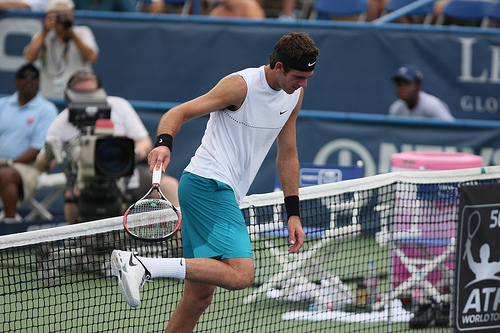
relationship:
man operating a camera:
[35, 68, 184, 242] [63, 90, 142, 278]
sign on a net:
[439, 182, 485, 323] [20, 171, 482, 321]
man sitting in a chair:
[0, 64, 58, 225] [19, 158, 64, 227]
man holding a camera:
[19, 0, 100, 104] [52, 10, 78, 40]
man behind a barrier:
[384, 57, 467, 123] [309, 114, 479, 212]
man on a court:
[106, 31, 321, 333] [25, 125, 472, 317]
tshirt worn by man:
[180, 67, 307, 200] [106, 31, 321, 333]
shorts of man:
[178, 168, 258, 261] [106, 31, 321, 333]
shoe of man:
[111, 249, 147, 309] [97, 23, 323, 330]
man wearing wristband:
[106, 31, 321, 333] [281, 191, 303, 217]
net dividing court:
[2, 166, 452, 331] [6, 208, 423, 329]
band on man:
[270, 51, 318, 73] [106, 31, 321, 333]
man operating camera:
[35, 68, 184, 242] [64, 70, 135, 224]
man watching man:
[0, 64, 58, 225] [106, 31, 321, 333]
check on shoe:
[128, 253, 137, 266] [107, 249, 148, 305]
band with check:
[270, 51, 318, 73] [308, 61, 316, 67]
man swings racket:
[106, 31, 321, 333] [119, 158, 183, 242]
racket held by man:
[119, 158, 183, 242] [111, 32, 318, 326]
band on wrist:
[284, 195, 301, 220] [288, 204, 298, 222]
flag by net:
[444, 183, 484, 328] [2, 166, 452, 331]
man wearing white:
[97, 23, 323, 330] [201, 70, 306, 215]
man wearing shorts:
[97, 23, 323, 330] [178, 168, 253, 261]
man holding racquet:
[97, 23, 323, 330] [116, 169, 193, 248]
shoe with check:
[108, 244, 151, 314] [121, 249, 142, 269]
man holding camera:
[19, 5, 100, 110] [38, 10, 82, 51]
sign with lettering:
[457, 204, 499, 330] [464, 205, 498, 325]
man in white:
[384, 57, 467, 123] [387, 87, 454, 124]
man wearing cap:
[384, 57, 467, 123] [390, 58, 429, 86]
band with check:
[267, 41, 328, 73] [302, 59, 316, 69]